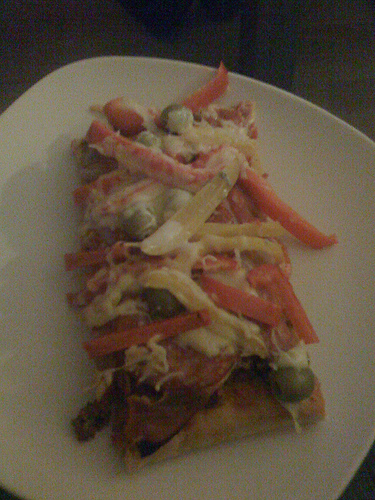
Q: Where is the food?
A: On a plate.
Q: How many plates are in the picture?
A: One.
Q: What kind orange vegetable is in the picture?
A: Carrots.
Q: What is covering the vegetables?
A: Sauce.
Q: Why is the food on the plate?
A: For eating.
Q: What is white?
A: Piece of onion.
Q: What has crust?
A: Sandwich.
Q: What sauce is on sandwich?
A: White sauce.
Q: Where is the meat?
A: On sandwich.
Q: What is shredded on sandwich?
A: Cheese.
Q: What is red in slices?
A: Red peppers.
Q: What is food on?
A: White plate.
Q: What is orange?
A: Sweet potatoes.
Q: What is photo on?
A: Bread with meat and veggies.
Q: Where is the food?
A: On a plate.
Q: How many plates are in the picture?
A: One.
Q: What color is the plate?
A: White.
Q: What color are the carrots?
A: Orange.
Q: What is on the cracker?
A: Vegetables.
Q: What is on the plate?
A: Food.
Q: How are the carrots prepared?
A: Sliced.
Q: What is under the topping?
A: Crust.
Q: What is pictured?
A: Food.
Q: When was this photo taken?
A: At meal time.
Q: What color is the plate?
A: White.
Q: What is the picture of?
A: Food.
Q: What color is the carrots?
A: Orange.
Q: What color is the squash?
A: Yellow.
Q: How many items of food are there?
A: 1.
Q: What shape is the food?
A: Rectangle.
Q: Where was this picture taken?
A: In a restaurant.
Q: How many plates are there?
A: 1.